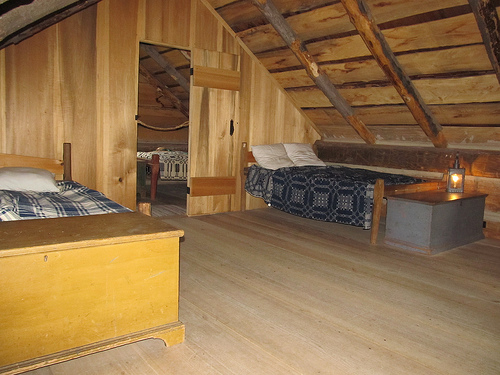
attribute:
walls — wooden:
[2, 2, 322, 218]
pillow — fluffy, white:
[252, 144, 296, 170]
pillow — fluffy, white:
[283, 142, 325, 166]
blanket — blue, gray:
[247, 163, 425, 230]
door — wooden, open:
[187, 47, 248, 221]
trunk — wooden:
[0, 210, 185, 375]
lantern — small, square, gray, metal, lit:
[447, 155, 466, 194]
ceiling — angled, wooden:
[205, 1, 500, 150]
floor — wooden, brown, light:
[3, 208, 500, 373]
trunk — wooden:
[384, 187, 488, 258]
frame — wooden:
[241, 140, 451, 246]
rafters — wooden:
[208, 2, 498, 151]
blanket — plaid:
[1, 180, 134, 223]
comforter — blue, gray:
[245, 165, 427, 231]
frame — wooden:
[0, 144, 71, 184]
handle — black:
[229, 120, 236, 136]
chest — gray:
[384, 182, 488, 258]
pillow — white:
[1, 167, 58, 194]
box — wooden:
[383, 189, 487, 261]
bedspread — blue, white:
[2, 179, 134, 227]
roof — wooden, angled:
[206, 2, 499, 149]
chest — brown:
[3, 211, 188, 375]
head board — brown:
[2, 141, 72, 185]